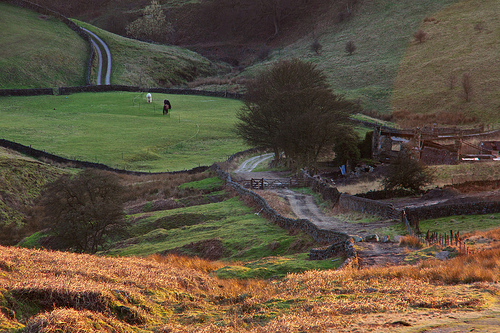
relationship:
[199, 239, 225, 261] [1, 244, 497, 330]
rock behind grass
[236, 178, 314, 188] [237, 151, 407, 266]
fence across road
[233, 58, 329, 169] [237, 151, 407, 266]
tree by road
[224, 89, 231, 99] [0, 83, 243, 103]
post on fence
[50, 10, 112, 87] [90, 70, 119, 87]
road goes down